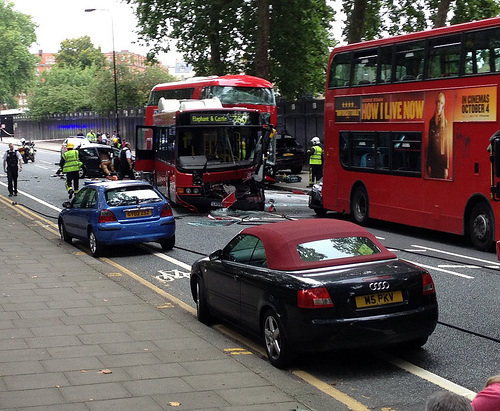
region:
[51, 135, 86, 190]
man wearing a green safety vest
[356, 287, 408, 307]
a yellow and black license plate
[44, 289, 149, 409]
gray blocks in the sidewalk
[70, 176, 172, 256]
a blue car parked on the curb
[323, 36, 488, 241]
a large red double decker bus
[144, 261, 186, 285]
a white bike symbol on the street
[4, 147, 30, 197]
a policeman wearing a white shirt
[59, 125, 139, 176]
a car accident in the street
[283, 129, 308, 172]
a black car on the sidewalk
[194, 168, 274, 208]
the damage front end of a bus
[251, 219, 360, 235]
red roof of car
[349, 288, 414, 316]
yellow license plate on car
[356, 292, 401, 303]
black lettering on plate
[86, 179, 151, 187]
blue roof top of car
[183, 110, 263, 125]
banner on top of bus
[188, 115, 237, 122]
green lettering on banner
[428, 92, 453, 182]
picture of woman on bus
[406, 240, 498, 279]
white lines on street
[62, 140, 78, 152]
worker wears yellow helmet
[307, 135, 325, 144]
worker wears white helmet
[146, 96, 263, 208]
A wrecked red bus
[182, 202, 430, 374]
A black sedan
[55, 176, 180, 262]
A blue hatchback car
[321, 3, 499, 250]
A red double-decker bus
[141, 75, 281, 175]
A red double-decker bus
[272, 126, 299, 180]
A black hatchback car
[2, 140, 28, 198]
A police officer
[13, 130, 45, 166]
A motorcycle on the road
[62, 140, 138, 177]
A wrecked black hatchback car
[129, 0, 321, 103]
A pair of tall, full trees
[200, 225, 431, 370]
black car with red top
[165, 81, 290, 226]
A smashed up front of bus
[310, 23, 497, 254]
A red double decker bus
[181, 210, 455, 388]
A black convertible with red top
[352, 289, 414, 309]
Yellow and black license plate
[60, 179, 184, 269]
A blue car parked at curb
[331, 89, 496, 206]
Advertisement on side of bus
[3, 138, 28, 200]
A man in a bullet proof vest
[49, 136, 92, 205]
A man in a green neon vest and yellow hat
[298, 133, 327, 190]
Man in green neon vest and white hat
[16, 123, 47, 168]
A motorcycle parked on the street